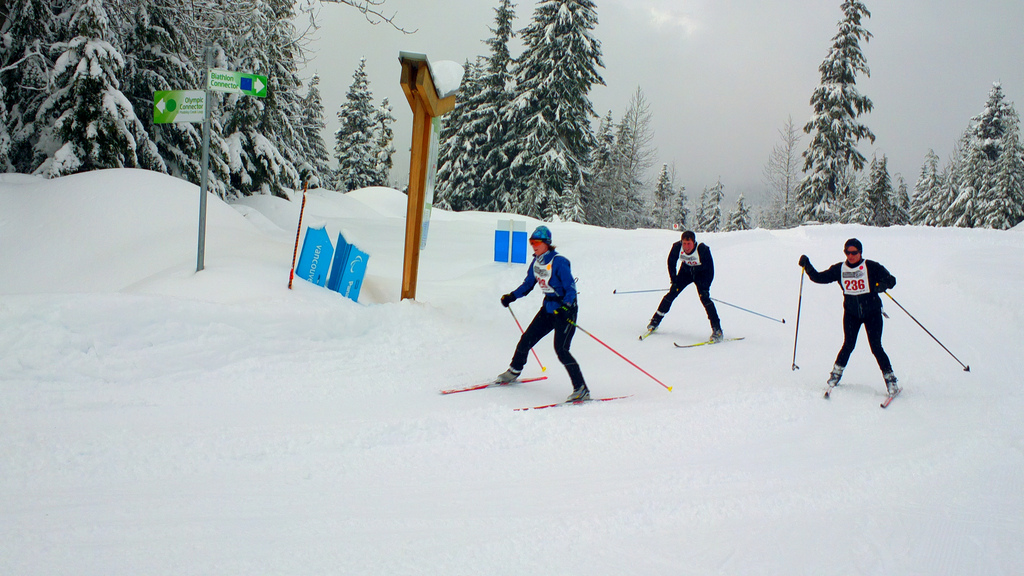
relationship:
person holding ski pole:
[609, 225, 788, 362] [711, 297, 787, 330]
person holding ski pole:
[609, 225, 788, 362] [613, 277, 674, 299]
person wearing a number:
[788, 228, 978, 405] [840, 268, 875, 295]